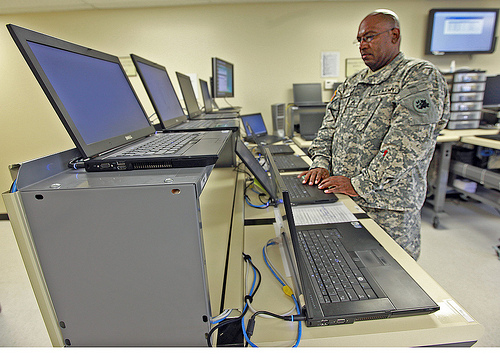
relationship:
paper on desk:
[282, 190, 357, 224] [237, 160, 367, 221]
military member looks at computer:
[292, 9, 449, 220] [132, 48, 193, 129]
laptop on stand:
[3, 21, 239, 169] [52, 173, 285, 263]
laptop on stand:
[127, 50, 241, 132] [52, 173, 285, 263]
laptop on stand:
[171, 70, 242, 122] [52, 173, 285, 263]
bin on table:
[434, 62, 488, 133] [433, 122, 498, 146]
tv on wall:
[422, 4, 498, 60] [4, 0, 499, 205]